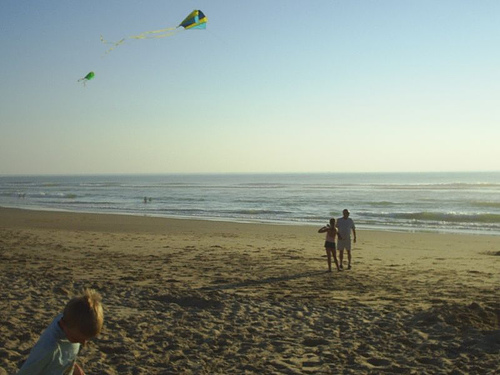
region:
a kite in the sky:
[102, 7, 237, 58]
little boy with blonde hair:
[0, 272, 116, 363]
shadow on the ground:
[148, 257, 320, 322]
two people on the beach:
[292, 175, 377, 294]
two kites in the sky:
[51, 2, 234, 93]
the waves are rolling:
[352, 181, 492, 235]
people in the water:
[122, 179, 174, 224]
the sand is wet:
[3, 204, 218, 241]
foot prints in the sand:
[263, 312, 409, 369]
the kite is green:
[30, 45, 122, 110]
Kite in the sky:
[14, 12, 271, 172]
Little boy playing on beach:
[11, 275, 150, 368]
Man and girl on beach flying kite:
[296, 206, 380, 311]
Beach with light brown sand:
[21, 210, 405, 343]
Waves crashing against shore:
[318, 198, 495, 241]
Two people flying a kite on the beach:
[207, 208, 405, 289]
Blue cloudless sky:
[198, 46, 458, 115]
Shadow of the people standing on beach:
[163, 257, 352, 324]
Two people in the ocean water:
[128, 185, 184, 232]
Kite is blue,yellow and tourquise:
[65, 0, 215, 101]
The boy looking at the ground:
[10, 273, 110, 373]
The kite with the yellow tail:
[88, 6, 213, 59]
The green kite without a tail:
[69, 65, 98, 92]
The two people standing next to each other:
[314, 203, 361, 275]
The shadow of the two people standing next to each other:
[168, 264, 329, 305]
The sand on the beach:
[0, 206, 497, 373]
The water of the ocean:
[0, 170, 498, 235]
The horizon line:
[1, 166, 497, 177]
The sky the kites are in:
[0, 0, 499, 172]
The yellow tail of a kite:
[95, 22, 181, 54]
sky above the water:
[277, 5, 323, 46]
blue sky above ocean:
[315, 12, 380, 47]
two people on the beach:
[293, 185, 377, 285]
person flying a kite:
[313, 210, 344, 256]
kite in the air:
[66, 67, 113, 107]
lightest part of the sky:
[394, 105, 474, 168]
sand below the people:
[233, 231, 284, 270]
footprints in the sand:
[210, 297, 295, 358]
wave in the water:
[245, 190, 300, 235]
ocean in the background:
[345, 157, 386, 183]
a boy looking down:
[38, 286, 113, 363]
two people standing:
[316, 198, 378, 275]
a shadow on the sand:
[207, 273, 297, 303]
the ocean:
[247, 172, 362, 214]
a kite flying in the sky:
[167, 8, 222, 43]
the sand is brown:
[77, 242, 151, 290]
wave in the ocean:
[411, 204, 468, 225]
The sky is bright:
[301, 81, 422, 153]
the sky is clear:
[250, 70, 385, 140]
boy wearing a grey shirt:
[40, 337, 70, 361]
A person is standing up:
[314, 213, 346, 273]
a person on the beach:
[318, 196, 370, 264]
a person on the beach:
[29, 256, 95, 338]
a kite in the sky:
[65, 43, 132, 101]